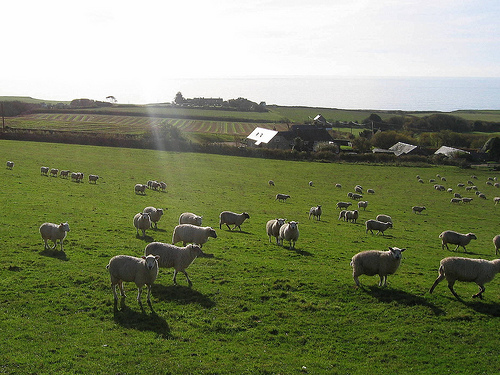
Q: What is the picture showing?
A: It is showing a pasture.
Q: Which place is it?
A: It is a pasture.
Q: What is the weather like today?
A: It is cloudy.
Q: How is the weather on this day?
A: It is cloudy.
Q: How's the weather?
A: It is cloudy.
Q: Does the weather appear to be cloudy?
A: Yes, it is cloudy.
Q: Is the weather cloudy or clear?
A: It is cloudy.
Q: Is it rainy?
A: No, it is cloudy.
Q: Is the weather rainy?
A: No, it is cloudy.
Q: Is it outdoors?
A: Yes, it is outdoors.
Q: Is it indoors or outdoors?
A: It is outdoors.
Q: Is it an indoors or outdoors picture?
A: It is outdoors.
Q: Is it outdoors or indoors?
A: It is outdoors.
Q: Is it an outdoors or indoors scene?
A: It is outdoors.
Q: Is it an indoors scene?
A: No, it is outdoors.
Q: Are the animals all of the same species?
A: Yes, all the animals are sheep.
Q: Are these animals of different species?
A: No, all the animals are sheep.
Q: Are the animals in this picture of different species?
A: No, all the animals are sheep.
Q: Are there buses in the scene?
A: No, there are no buses.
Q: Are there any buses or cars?
A: No, there are no buses or cars.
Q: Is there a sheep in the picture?
A: Yes, there is a sheep.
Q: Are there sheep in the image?
A: Yes, there is a sheep.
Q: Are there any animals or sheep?
A: Yes, there is a sheep.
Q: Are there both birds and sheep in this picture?
A: No, there is a sheep but no birds.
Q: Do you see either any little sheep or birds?
A: Yes, there is a little sheep.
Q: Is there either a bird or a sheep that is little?
A: Yes, the sheep is little.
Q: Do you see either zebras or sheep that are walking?
A: Yes, the sheep is walking.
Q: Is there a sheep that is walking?
A: Yes, there is a sheep that is walking.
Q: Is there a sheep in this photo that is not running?
A: Yes, there is a sheep that is walking.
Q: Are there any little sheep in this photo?
A: Yes, there is a little sheep.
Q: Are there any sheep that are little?
A: Yes, there is a sheep that is little.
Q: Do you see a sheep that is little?
A: Yes, there is a sheep that is little.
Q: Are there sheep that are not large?
A: Yes, there is a little sheep.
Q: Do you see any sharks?
A: No, there are no sharks.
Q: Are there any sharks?
A: No, there are no sharks.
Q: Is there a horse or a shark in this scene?
A: No, there are no sharks or horses.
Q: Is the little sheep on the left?
A: Yes, the sheep is on the left of the image.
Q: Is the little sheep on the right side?
A: No, the sheep is on the left of the image.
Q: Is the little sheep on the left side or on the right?
A: The sheep is on the left of the image.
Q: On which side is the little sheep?
A: The sheep is on the left of the image.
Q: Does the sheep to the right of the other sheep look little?
A: Yes, the sheep is little.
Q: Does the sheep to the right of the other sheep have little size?
A: Yes, the sheep is little.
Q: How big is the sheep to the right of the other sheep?
A: The sheep is little.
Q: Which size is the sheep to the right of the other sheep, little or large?
A: The sheep is little.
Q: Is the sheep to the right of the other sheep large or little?
A: The sheep is little.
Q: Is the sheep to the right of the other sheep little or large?
A: The sheep is little.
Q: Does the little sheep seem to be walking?
A: Yes, the sheep is walking.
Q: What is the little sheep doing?
A: The sheep is walking.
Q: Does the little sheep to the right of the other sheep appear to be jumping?
A: No, the sheep is walking.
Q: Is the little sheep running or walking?
A: The sheep is walking.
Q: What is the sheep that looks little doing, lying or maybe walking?
A: The sheep is walking.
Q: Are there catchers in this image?
A: No, there are no catchers.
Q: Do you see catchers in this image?
A: No, there are no catchers.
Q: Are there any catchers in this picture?
A: No, there are no catchers.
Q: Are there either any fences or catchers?
A: No, there are no catchers or fences.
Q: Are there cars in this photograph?
A: No, there are no cars.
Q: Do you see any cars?
A: No, there are no cars.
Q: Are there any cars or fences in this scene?
A: No, there are no cars or fences.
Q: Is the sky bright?
A: Yes, the sky is bright.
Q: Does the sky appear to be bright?
A: Yes, the sky is bright.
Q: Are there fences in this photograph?
A: No, there are no fences.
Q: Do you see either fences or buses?
A: No, there are no fences or buses.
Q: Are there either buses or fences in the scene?
A: No, there are no fences or buses.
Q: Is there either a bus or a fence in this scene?
A: No, there are no fences or buses.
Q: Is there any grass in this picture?
A: Yes, there is grass.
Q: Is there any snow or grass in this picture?
A: Yes, there is grass.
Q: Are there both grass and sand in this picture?
A: No, there is grass but no sand.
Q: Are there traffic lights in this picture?
A: No, there are no traffic lights.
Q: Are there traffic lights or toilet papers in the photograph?
A: No, there are no traffic lights or toilet papers.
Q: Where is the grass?
A: The grass is on the pasture.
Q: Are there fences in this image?
A: No, there are no fences.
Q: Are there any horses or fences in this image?
A: No, there are no fences or horses.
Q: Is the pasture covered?
A: Yes, the pasture is covered.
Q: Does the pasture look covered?
A: Yes, the pasture is covered.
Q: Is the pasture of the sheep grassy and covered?
A: Yes, the pasture is grassy and covered.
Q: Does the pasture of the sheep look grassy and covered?
A: Yes, the pasture is grassy and covered.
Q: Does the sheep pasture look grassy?
A: Yes, the pasture is grassy.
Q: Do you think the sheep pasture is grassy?
A: Yes, the pasture is grassy.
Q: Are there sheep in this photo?
A: Yes, there is a sheep.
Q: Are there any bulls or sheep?
A: Yes, there is a sheep.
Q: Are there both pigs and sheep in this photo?
A: No, there is a sheep but no pigs.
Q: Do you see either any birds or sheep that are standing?
A: Yes, the sheep is standing.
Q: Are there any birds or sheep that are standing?
A: Yes, the sheep is standing.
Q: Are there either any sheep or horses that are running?
A: Yes, the sheep is running.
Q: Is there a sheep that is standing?
A: Yes, there is a sheep that is standing.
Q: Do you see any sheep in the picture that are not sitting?
A: Yes, there is a sheep that is standing .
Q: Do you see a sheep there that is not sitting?
A: Yes, there is a sheep that is standing .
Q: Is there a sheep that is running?
A: Yes, there is a sheep that is running.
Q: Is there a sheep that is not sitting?
A: Yes, there is a sheep that is running.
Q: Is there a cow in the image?
A: No, there are no cows.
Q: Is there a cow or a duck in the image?
A: No, there are no cows or ducks.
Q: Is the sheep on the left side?
A: Yes, the sheep is on the left of the image.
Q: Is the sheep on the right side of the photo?
A: No, the sheep is on the left of the image.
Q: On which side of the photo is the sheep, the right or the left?
A: The sheep is on the left of the image.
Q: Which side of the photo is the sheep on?
A: The sheep is on the left of the image.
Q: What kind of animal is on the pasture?
A: The animal is a sheep.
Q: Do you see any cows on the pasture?
A: No, there is a sheep on the pasture.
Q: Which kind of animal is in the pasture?
A: The animal is a sheep.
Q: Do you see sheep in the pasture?
A: Yes, there is a sheep in the pasture.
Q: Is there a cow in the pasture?
A: No, there is a sheep in the pasture.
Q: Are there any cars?
A: No, there are no cars.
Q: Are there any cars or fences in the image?
A: No, there are no cars or fences.